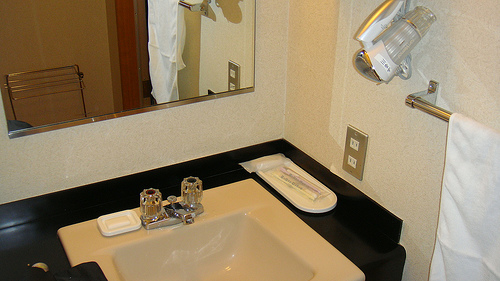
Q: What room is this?
A: It is a bathroom.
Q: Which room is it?
A: It is a bathroom.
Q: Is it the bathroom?
A: Yes, it is the bathroom.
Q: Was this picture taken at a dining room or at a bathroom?
A: It was taken at a bathroom.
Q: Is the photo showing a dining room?
A: No, the picture is showing a bathroom.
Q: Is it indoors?
A: Yes, it is indoors.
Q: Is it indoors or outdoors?
A: It is indoors.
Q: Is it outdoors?
A: No, it is indoors.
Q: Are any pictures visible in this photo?
A: No, there are no pictures.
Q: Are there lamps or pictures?
A: No, there are no pictures or lamps.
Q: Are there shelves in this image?
A: No, there are no shelves.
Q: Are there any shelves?
A: No, there are no shelves.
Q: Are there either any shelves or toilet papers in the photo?
A: No, there are no shelves or toilet papers.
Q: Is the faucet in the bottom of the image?
A: Yes, the faucet is in the bottom of the image.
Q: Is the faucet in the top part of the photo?
A: No, the faucet is in the bottom of the image.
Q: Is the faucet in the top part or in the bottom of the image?
A: The faucet is in the bottom of the image.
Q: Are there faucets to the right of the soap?
A: Yes, there is a faucet to the right of the soap.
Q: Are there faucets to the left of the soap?
A: No, the faucet is to the right of the soap.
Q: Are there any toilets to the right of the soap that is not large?
A: No, there is a faucet to the right of the soap.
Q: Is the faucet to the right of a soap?
A: Yes, the faucet is to the right of a soap.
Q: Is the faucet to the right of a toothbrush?
A: No, the faucet is to the right of a soap.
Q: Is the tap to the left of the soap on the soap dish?
A: No, the tap is to the right of the soap.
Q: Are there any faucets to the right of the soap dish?
A: Yes, there is a faucet to the right of the soap dish.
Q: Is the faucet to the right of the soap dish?
A: Yes, the faucet is to the right of the soap dish.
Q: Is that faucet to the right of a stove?
A: No, the faucet is to the right of the soap dish.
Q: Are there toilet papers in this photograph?
A: No, there are no toilet papers.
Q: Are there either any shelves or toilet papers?
A: No, there are no toilet papers or shelves.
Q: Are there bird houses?
A: No, there are no bird houses.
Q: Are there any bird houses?
A: No, there are no bird houses.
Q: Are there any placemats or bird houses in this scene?
A: No, there are no bird houses or placemats.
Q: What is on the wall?
A: The outlet is on the wall.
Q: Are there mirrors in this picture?
A: Yes, there is a mirror.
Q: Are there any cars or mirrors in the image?
A: Yes, there is a mirror.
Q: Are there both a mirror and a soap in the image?
A: Yes, there are both a mirror and a soap.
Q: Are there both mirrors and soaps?
A: Yes, there are both a mirror and a soap.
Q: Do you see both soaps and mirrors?
A: Yes, there are both a mirror and a soap.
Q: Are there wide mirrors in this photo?
A: Yes, there is a wide mirror.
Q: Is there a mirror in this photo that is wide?
A: Yes, there is a mirror that is wide.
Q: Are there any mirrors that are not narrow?
A: Yes, there is a wide mirror.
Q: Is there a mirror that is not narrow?
A: Yes, there is a wide mirror.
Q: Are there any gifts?
A: No, there are no gifts.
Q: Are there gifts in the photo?
A: No, there are no gifts.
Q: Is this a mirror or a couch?
A: This is a mirror.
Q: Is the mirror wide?
A: Yes, the mirror is wide.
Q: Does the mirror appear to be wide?
A: Yes, the mirror is wide.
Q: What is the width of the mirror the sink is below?
A: The mirror is wide.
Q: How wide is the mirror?
A: The mirror is wide.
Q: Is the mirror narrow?
A: No, the mirror is wide.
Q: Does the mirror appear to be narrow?
A: No, the mirror is wide.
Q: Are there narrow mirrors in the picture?
A: No, there is a mirror but it is wide.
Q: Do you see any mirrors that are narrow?
A: No, there is a mirror but it is wide.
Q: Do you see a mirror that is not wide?
A: No, there is a mirror but it is wide.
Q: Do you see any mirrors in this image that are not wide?
A: No, there is a mirror but it is wide.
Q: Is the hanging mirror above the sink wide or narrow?
A: The mirror is wide.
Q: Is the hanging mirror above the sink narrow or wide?
A: The mirror is wide.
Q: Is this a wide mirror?
A: Yes, this is a wide mirror.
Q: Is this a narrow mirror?
A: No, this is a wide mirror.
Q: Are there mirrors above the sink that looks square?
A: Yes, there is a mirror above the sink.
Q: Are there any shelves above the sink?
A: No, there is a mirror above the sink.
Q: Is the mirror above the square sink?
A: Yes, the mirror is above the sink.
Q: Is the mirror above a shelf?
A: No, the mirror is above the sink.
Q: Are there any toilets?
A: No, there are no toilets.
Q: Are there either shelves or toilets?
A: No, there are no toilets or shelves.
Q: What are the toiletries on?
A: The toiletries are on the counter.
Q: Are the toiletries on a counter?
A: Yes, the toiletries are on a counter.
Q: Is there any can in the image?
A: No, there are no cans.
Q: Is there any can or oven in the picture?
A: No, there are no cans or ovens.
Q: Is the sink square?
A: Yes, the sink is square.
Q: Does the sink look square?
A: Yes, the sink is square.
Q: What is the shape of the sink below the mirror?
A: The sink is square.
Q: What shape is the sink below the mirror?
A: The sink is square.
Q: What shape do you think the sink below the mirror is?
A: The sink is square.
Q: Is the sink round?
A: No, the sink is square.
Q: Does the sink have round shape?
A: No, the sink is square.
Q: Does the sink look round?
A: No, the sink is square.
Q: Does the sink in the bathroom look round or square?
A: The sink is square.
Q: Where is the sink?
A: The sink is in the bathroom.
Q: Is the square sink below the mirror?
A: Yes, the sink is below the mirror.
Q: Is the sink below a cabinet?
A: No, the sink is below the mirror.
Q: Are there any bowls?
A: No, there are no bowls.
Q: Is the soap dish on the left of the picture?
A: Yes, the soap dish is on the left of the image.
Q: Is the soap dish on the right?
A: No, the soap dish is on the left of the image.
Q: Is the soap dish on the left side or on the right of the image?
A: The soap dish is on the left of the image.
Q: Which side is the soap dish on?
A: The soap dish is on the left of the image.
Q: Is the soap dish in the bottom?
A: Yes, the soap dish is in the bottom of the image.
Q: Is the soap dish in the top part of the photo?
A: No, the soap dish is in the bottom of the image.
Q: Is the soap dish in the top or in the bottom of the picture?
A: The soap dish is in the bottom of the image.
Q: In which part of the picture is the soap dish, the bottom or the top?
A: The soap dish is in the bottom of the image.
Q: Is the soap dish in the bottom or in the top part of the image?
A: The soap dish is in the bottom of the image.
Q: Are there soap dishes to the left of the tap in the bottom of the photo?
A: Yes, there is a soap dish to the left of the tap.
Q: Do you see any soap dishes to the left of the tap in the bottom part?
A: Yes, there is a soap dish to the left of the tap.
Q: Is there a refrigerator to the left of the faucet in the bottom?
A: No, there is a soap dish to the left of the tap.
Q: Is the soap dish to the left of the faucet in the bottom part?
A: Yes, the soap dish is to the left of the tap.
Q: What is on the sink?
A: The soap dish is on the sink.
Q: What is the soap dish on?
A: The soap dish is on the sink.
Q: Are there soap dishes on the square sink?
A: Yes, there is a soap dish on the sink.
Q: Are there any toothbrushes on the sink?
A: No, there is a soap dish on the sink.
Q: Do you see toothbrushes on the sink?
A: No, there is a soap dish on the sink.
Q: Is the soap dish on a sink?
A: Yes, the soap dish is on a sink.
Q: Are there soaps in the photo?
A: Yes, there is a soap.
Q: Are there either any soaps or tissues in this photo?
A: Yes, there is a soap.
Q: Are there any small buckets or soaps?
A: Yes, there is a small soap.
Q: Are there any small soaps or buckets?
A: Yes, there is a small soap.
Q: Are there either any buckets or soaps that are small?
A: Yes, the soap is small.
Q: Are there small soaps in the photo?
A: Yes, there is a small soap.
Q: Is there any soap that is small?
A: Yes, there is a soap that is small.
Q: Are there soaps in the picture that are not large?
A: Yes, there is a small soap.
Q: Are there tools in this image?
A: No, there are no tools.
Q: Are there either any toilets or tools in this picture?
A: No, there are no tools or toilets.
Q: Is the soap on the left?
A: Yes, the soap is on the left of the image.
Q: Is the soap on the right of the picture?
A: No, the soap is on the left of the image.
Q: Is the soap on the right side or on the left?
A: The soap is on the left of the image.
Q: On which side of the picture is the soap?
A: The soap is on the left of the image.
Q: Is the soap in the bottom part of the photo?
A: Yes, the soap is in the bottom of the image.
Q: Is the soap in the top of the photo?
A: No, the soap is in the bottom of the image.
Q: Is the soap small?
A: Yes, the soap is small.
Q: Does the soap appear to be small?
A: Yes, the soap is small.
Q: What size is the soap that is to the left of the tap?
A: The soap is small.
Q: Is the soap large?
A: No, the soap is small.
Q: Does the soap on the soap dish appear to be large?
A: No, the soap is small.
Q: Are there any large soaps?
A: No, there is a soap but it is small.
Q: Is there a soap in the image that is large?
A: No, there is a soap but it is small.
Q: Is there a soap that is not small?
A: No, there is a soap but it is small.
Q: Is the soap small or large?
A: The soap is small.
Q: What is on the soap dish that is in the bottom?
A: The soap is on the soap dish.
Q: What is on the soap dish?
A: The soap is on the soap dish.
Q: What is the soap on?
A: The soap is on the soap dish.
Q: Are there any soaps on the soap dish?
A: Yes, there is a soap on the soap dish.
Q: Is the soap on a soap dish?
A: Yes, the soap is on a soap dish.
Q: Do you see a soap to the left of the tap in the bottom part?
A: Yes, there is a soap to the left of the tap.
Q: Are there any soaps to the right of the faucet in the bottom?
A: No, the soap is to the left of the tap.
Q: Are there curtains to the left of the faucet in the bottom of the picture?
A: No, there is a soap to the left of the faucet.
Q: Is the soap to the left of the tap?
A: Yes, the soap is to the left of the tap.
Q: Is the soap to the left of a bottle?
A: No, the soap is to the left of the tap.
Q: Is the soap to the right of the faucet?
A: No, the soap is to the left of the faucet.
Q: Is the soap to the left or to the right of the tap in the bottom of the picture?
A: The soap is to the left of the tap.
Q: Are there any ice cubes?
A: No, there are no ice cubes.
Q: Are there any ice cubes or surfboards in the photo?
A: No, there are no ice cubes or surfboards.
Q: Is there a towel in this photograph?
A: Yes, there is a towel.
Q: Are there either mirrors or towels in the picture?
A: Yes, there is a towel.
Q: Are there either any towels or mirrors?
A: Yes, there is a towel.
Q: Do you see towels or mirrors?
A: Yes, there is a towel.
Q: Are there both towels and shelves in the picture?
A: No, there is a towel but no shelves.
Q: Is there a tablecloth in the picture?
A: No, there are no tablecloths.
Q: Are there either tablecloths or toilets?
A: No, there are no tablecloths or toilets.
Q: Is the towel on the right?
A: Yes, the towel is on the right of the image.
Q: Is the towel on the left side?
A: No, the towel is on the right of the image.